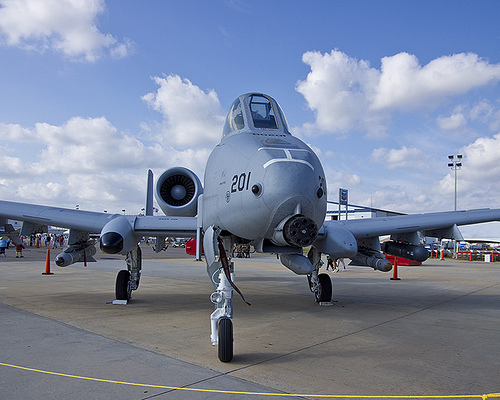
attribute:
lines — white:
[258, 143, 323, 171]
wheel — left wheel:
[111, 261, 148, 307]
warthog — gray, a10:
[8, 85, 497, 387]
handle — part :
[218, 312, 233, 317]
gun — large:
[280, 211, 321, 248]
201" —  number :
[228, 169, 256, 196]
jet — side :
[2, 70, 497, 364]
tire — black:
[200, 318, 269, 368]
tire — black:
[102, 266, 149, 307]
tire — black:
[297, 265, 334, 300]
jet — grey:
[101, 130, 451, 287]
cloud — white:
[2, 0, 134, 61]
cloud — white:
[142, 74, 224, 148]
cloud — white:
[295, 50, 376, 137]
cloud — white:
[375, 51, 495, 106]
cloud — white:
[440, 114, 464, 132]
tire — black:
[201, 312, 259, 360]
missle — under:
[52, 237, 98, 270]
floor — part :
[1, 244, 498, 396]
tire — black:
[205, 314, 248, 362]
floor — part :
[0, 260, 490, 397]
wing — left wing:
[2, 197, 199, 262]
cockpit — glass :
[224, 91, 291, 135]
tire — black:
[114, 267, 131, 304]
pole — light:
[445, 153, 463, 210]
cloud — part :
[303, 49, 398, 144]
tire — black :
[214, 317, 239, 364]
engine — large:
[153, 165, 201, 217]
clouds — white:
[2, 73, 228, 217]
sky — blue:
[3, 1, 499, 242]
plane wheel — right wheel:
[319, 270, 334, 307]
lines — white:
[257, 145, 317, 168]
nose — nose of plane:
[222, 139, 329, 239]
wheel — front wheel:
[196, 307, 261, 361]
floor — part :
[1, 252, 497, 389]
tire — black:
[307, 268, 337, 308]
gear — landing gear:
[189, 233, 258, 371]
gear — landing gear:
[191, 260, 245, 371]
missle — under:
[371, 243, 439, 275]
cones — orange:
[14, 242, 424, 292]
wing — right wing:
[4, 169, 200, 258]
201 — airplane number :
[229, 170, 258, 193]